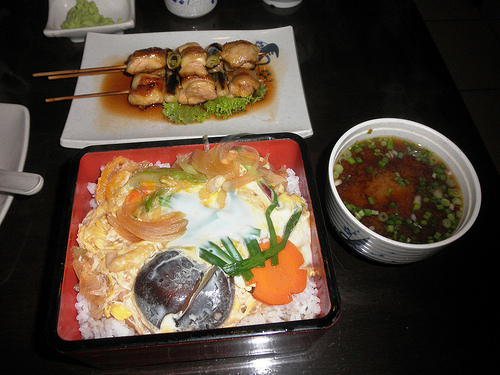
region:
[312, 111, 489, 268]
a white bowl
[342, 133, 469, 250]
green onions in soup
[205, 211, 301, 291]
green beans on a plate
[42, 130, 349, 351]
a red and black square dish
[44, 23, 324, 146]
a square white dish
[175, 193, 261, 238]
white cream liquid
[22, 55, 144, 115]
skewer sticks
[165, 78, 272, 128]
green garnish on the plate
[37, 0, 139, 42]
white dish full of wasabi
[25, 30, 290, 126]
meat on a stick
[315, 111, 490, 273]
bowl of miso soup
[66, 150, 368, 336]
a bento box of food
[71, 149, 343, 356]
Japanese food in a box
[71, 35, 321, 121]
skewers of fish on a plate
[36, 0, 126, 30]
a plate of wasabi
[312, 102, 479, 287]
small bowl of soup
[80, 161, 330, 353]
mix of egg, sauce, and vegetables over a bed of rice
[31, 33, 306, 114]
plated skewers of food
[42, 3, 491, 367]
dinner on a table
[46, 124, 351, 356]
a black box of food with a red interior lining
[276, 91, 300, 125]
this is a plate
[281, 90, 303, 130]
the plate is flat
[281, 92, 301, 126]
the plate is white in color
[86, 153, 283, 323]
the food is on the plate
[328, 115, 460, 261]
this is a bowl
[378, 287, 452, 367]
the table is brown in color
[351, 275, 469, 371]
the table is wooden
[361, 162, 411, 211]
this is a soup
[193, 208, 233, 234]
this is a milk in the middle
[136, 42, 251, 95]
this is fried beef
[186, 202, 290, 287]
green beans on the plate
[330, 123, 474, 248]
green onions in the soup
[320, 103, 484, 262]
a white bowl of soup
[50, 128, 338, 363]
an orange and black square dish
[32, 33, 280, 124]
meat on skewers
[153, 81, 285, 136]
lettuce garnish on the plate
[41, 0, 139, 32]
wasabi sauce in a white dish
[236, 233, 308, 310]
orange circle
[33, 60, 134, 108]
skewering sticks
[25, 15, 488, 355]
food on a table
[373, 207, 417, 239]
Green onions in a soup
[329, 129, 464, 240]
Brown soup in a bowl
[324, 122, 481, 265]
White bowl on a table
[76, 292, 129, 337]
Rice in a red platter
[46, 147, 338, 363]
Black plate with a red lining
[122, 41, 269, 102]
Chicken on wooden skewers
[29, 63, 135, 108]
Wooden skewers on a white plate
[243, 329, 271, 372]
Light reflecting off a plate and table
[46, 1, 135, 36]
Green wasabi in a white plate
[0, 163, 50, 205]
White utensil on a white plate